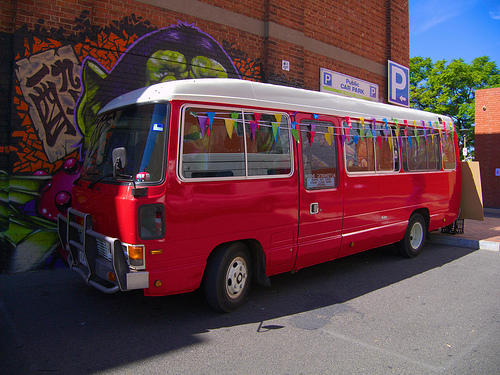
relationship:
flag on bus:
[196, 114, 206, 136] [55, 77, 464, 314]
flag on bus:
[206, 109, 216, 128] [55, 77, 464, 314]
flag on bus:
[221, 116, 235, 137] [55, 77, 464, 314]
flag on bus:
[246, 121, 258, 138] [55, 77, 464, 314]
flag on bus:
[268, 121, 280, 137] [55, 77, 464, 314]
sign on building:
[320, 70, 382, 103] [4, 4, 410, 271]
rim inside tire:
[226, 264, 247, 289] [201, 238, 260, 314]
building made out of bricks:
[2, 2, 405, 298] [332, 17, 382, 49]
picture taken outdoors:
[0, 0, 500, 375] [12, 27, 497, 365]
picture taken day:
[28, 21, 483, 363] [10, 9, 495, 374]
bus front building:
[55, 77, 464, 314] [9, 9, 409, 325]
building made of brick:
[9, 9, 409, 325] [38, 7, 83, 21]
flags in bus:
[189, 101, 464, 152] [58, 76, 460, 308]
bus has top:
[48, 60, 482, 314] [94, 64, 465, 132]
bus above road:
[55, 77, 464, 314] [1, 241, 498, 373]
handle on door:
[309, 200, 319, 213] [295, 113, 342, 267]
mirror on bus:
[109, 146, 129, 172] [55, 77, 464, 314]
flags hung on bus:
[175, 96, 461, 172] [58, 76, 460, 308]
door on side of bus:
[295, 113, 342, 267] [58, 76, 460, 308]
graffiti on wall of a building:
[9, 21, 252, 271] [4, 4, 410, 271]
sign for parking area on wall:
[389, 61, 411, 104] [269, 14, 401, 54]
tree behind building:
[405, 53, 498, 126] [4, 4, 410, 271]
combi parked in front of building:
[15, 3, 477, 313] [230, 50, 321, 80]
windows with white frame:
[175, 108, 288, 174] [173, 95, 468, 182]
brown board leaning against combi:
[462, 158, 486, 222] [56, 79, 463, 315]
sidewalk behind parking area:
[432, 215, 499, 250] [4, 239, 496, 374]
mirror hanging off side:
[109, 142, 138, 182] [117, 122, 187, 282]